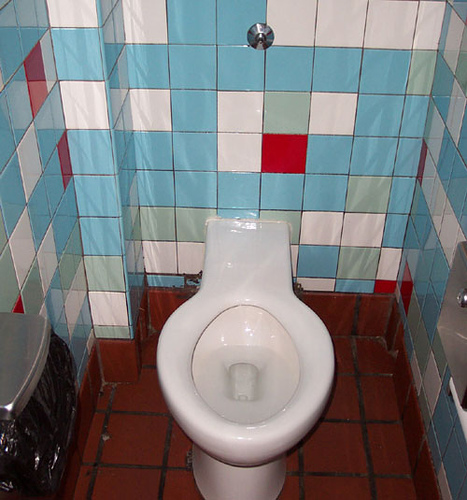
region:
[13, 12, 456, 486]
white toilet in tiled room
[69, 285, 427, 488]
deep red tiles with dark grout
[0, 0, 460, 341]
random pattern of blue, white, gray and red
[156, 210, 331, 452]
oval opening on smooth rim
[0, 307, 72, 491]
plastic bag hanging under metal lid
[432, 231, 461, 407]
metal container with keyhole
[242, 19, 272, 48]
silver button in metal ring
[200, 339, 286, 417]
water at bottom of toilet bowl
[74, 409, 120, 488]
bits of litter on floor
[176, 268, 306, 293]
black residue behind toilet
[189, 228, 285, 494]
toilet basin is white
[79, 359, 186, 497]
floor tile is red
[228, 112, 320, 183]
a red tile in middle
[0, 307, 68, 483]
waste container to the right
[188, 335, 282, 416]
water in the toilet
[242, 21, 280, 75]
metal flusher in the wall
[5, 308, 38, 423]
top of can is silver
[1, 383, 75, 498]
large plastic cover on can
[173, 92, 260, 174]
blue and white tile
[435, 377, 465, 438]
paper dispenser to the left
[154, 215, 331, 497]
white clean toilet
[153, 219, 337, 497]
white toilet in bathroom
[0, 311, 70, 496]
gray metal dump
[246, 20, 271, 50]
small gray metal knob in the wall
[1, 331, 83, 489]
black bag in paper bin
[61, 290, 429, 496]
orange floor with bloack toilet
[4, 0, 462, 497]
walls are light blue red and white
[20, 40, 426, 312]
red ceramics on wall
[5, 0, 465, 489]
light blue ceramics on wall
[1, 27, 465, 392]
aqua green ceramics on wall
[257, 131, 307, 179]
Single red tile on wall face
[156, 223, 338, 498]
Clean toilet with no back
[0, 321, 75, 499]
Shiny silver trash can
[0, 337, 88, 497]
Black trash bag hanging out of trash can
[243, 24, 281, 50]
Small Silver flush button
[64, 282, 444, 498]
Red floor tiles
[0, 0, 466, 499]
Blue, red, white, and green wall tiles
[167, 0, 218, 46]
One blue wall tile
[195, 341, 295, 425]
Clear water in toilet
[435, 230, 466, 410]
Silver box next to toilet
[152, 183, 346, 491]
toilet in a public restroom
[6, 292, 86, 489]
trash can in a restroom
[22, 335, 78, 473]
bag lining a trash can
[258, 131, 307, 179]
red tile square on the wall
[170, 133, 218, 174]
blue tile square on the wall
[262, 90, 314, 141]
green tile square on the wall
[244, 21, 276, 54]
flush button on the wall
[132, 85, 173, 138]
white tile square on the wall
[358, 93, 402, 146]
blue tile square on the wall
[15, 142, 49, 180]
white tile square on the wall